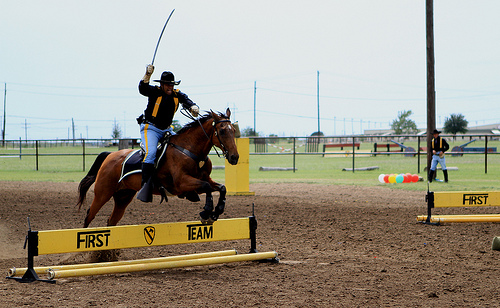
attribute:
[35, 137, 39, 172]
pole — wood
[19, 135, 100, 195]
pole — wood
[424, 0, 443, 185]
pole — wood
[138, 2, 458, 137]
cloud — white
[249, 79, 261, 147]
pole — wood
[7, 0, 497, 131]
clouds — white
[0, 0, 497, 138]
sky — blue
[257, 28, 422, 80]
clouds — white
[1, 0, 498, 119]
sky — blue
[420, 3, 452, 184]
pole — wood